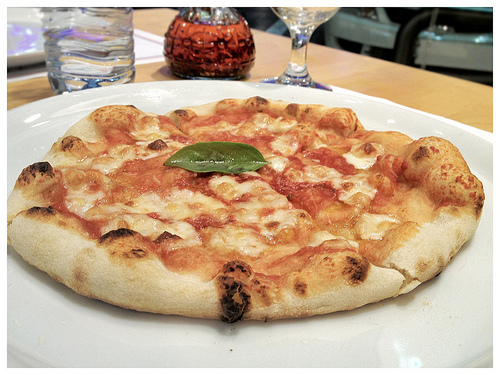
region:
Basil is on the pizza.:
[163, 142, 270, 174]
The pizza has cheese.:
[23, 96, 468, 307]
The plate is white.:
[11, 88, 489, 365]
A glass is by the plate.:
[266, 9, 336, 91]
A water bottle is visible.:
[33, 9, 143, 94]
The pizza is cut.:
[20, 92, 479, 315]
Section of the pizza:
[211, 213, 408, 338]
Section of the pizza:
[80, 218, 229, 325]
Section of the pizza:
[131, 129, 343, 243]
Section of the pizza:
[321, 148, 448, 276]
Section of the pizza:
[121, 163, 280, 306]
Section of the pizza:
[84, 96, 237, 216]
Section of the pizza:
[235, 76, 389, 258]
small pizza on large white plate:
[12, 82, 489, 364]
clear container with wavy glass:
[40, 8, 137, 93]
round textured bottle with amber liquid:
[162, 10, 257, 80]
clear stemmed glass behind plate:
[261, 8, 336, 95]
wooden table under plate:
[8, 11, 488, 137]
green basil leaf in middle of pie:
[17, 92, 482, 323]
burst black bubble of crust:
[215, 263, 252, 323]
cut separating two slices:
[273, 183, 423, 294]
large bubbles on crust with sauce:
[389, 125, 486, 212]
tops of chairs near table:
[320, 12, 490, 87]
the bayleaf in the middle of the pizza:
[166, 143, 267, 174]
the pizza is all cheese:
[34, 93, 470, 297]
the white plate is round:
[13, 80, 493, 365]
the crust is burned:
[215, 267, 262, 329]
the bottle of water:
[44, 9, 140, 89]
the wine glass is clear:
[278, 50, 339, 98]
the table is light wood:
[22, 48, 492, 125]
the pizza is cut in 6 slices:
[30, 97, 485, 311]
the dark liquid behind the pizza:
[172, 14, 249, 74]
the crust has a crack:
[372, 260, 426, 288]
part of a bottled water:
[38, 9, 138, 93]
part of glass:
[266, 9, 343, 90]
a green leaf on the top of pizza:
[164, 140, 264, 173]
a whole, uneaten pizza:
[13, 94, 486, 326]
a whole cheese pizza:
[9, 100, 484, 324]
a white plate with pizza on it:
[9, 80, 494, 369]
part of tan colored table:
[6, 8, 496, 130]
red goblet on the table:
[163, 8, 255, 76]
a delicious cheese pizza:
[12, 103, 483, 323]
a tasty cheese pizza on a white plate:
[9, 99, 483, 327]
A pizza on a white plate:
[8, 96, 488, 314]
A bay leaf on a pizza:
[159, 138, 266, 175]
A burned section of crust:
[213, 273, 252, 325]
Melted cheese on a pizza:
[137, 187, 212, 218]